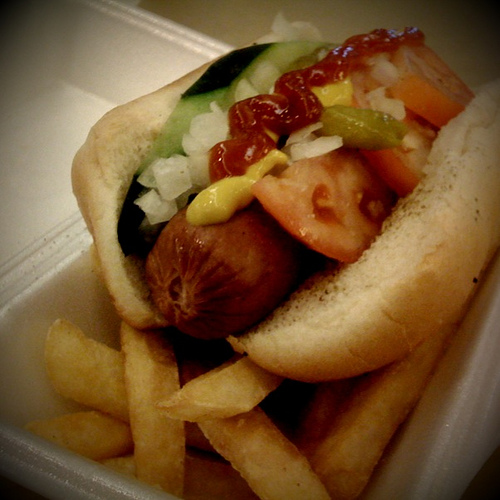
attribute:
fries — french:
[19, 271, 444, 481]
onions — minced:
[128, 99, 230, 226]